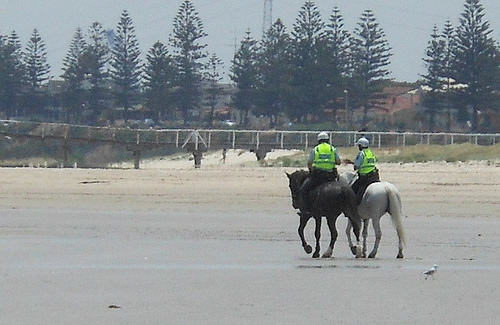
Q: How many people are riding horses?
A: 2.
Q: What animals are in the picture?
A: Horses and a bird.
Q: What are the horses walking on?
A: Sand.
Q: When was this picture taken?
A: During daylight.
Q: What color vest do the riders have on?
A: Bright green.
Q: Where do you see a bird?
A: Behind the horse.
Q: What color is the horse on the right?
A: White.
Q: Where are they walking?
A: Along the beach.